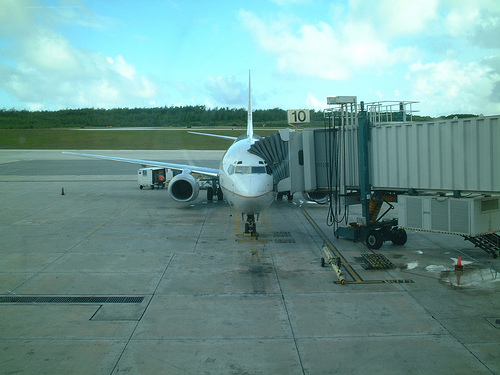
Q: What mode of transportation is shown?
A: Plane.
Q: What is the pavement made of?
A: Concrete.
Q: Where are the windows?
A: On the front of the plane.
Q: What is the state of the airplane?
A: Parked.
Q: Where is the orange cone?
A: Beside the water.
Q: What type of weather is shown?
A: Cloudy.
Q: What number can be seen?
A: 10.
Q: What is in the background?
A: Trees.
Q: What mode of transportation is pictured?
A: An airplane.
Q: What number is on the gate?
A: 10.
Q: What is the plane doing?
A: It is parked.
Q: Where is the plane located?
A: At the airport.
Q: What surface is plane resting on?
A: Cement.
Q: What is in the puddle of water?
A: Orange cones.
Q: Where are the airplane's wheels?
A: On the ground.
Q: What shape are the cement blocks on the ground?
A: Rectangles.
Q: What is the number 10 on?
A: A white sign.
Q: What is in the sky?
A: Clouds.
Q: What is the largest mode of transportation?
A: Plane.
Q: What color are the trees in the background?
A: Green.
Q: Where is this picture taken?
A: Airport.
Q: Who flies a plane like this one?
A: A pilot.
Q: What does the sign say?
A: 10.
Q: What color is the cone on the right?
A: Orange.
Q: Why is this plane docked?
A: To unload passengers.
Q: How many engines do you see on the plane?
A: One.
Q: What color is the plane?
A: White and grey.